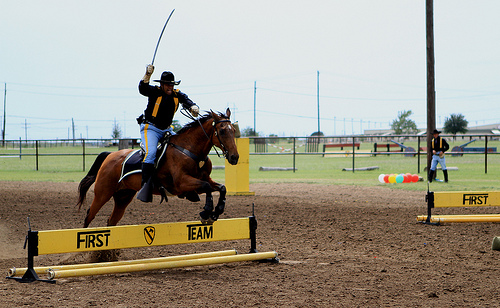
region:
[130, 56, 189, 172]
Man wearing bright blue jeans with a yellow stripe down the side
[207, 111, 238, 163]
Head of a brown colored horse wearing a harness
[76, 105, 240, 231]
Brown horse leaping over a yellow barrier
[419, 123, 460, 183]
Man wearing a black shirt and yellow suspenders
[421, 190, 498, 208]
Small wooden sign reading First in black writing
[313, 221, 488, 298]
Unevenly textured brown mud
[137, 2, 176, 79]
Metal sword being held in the air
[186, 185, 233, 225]
Two front hoofs of a horse prancing in the air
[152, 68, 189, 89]
Black ten gallon hat being worn by a person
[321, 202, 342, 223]
dark spot in dirt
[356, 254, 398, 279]
dark spot in dirt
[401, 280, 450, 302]
dark spot in dirt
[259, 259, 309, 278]
dark spot in dirt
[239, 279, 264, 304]
dark spot in dirt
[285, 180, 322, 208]
dark spot in dirt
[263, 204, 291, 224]
dark spot in dirt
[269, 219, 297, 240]
dark spot in dirt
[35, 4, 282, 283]
man riding horse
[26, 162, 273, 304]
horse jumping over obstacle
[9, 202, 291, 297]
obstacle is yellow and black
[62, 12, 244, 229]
man holding riding whip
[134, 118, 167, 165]
blue stripe on pants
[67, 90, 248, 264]
riding horse is brown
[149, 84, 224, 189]
black bridle on horse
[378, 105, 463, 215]
man standing in background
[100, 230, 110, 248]
black letter painted on yellow jumping post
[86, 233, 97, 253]
black letter painted on yellow jumping post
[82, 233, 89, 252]
black letter painted on yellow jumping post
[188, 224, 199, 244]
black letter painted on yellow jumping post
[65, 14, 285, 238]
person jumping a horse over a post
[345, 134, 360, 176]
black metal fence post in a field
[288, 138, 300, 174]
black metal fence post in a field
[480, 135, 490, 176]
black metal fence post in a field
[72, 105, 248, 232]
a large brown and black horse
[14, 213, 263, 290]
a long yellow and black obstacle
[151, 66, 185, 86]
a black hat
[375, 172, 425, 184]
a set of colorful balloons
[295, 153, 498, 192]
a section of green grass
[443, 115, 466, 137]
a large green tree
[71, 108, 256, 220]
brown horse jumping over obstacle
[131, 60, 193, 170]
man in costume riding brown horse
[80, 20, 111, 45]
white clouds in blue sky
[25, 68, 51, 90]
white clouds in blue sky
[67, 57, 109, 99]
white clouds in blue sky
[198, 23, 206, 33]
white clouds in blue sky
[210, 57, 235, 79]
white clouds in blue sky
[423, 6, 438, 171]
A pole made of wood.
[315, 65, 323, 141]
A pole made of wood.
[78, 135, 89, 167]
A pole made of wood.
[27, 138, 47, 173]
A pole made of wood.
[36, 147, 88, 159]
A pole made of wood.